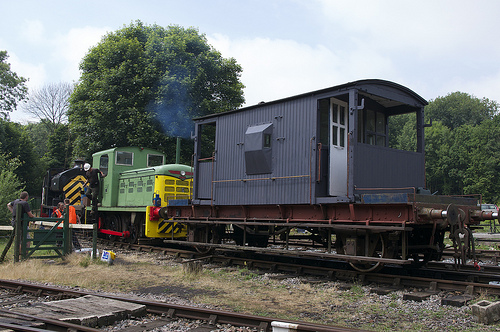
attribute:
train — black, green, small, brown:
[42, 75, 465, 257]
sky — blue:
[0, 1, 497, 97]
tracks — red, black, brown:
[177, 230, 482, 299]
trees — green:
[3, 22, 230, 166]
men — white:
[3, 191, 79, 226]